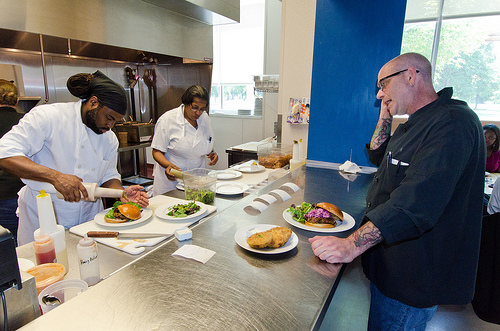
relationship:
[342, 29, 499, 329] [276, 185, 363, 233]
man waits for food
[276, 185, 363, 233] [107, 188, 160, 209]
food being prepared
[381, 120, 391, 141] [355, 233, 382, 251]
tattoo on arm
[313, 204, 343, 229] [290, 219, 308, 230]
burger on plate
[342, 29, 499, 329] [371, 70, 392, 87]
man wearing glasses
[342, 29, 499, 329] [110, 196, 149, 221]
man preparing meal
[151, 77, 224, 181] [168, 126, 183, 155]
woman wearing white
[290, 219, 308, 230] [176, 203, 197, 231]
plate has lettuce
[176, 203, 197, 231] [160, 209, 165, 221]
lettuce on side of dish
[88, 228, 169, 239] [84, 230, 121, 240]
knife with handle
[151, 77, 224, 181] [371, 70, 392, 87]
woman wearing glasses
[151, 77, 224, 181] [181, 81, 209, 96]
woman wearing hair net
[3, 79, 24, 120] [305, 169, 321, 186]
cook behind counter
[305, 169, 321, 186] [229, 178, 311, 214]
counter has four order tickets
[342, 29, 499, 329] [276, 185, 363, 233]
man getting food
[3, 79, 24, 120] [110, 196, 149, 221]
cook preparing a meal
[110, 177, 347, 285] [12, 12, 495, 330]
cooking area in kitchen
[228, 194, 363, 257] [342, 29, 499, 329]
two plates in front of man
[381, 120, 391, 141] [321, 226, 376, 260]
tattoo on lower arm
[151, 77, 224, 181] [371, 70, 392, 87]
woman has glasses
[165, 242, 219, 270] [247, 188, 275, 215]
paper has orders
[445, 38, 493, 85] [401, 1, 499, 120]
trees outside window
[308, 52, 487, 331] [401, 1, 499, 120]
man next to window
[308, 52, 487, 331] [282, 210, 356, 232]
man next to plate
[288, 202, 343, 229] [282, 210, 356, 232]
food on plate